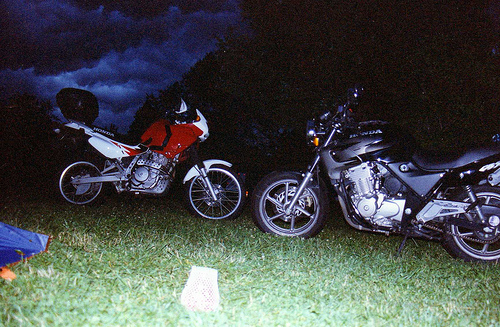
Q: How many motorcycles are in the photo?
A: Two.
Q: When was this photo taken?
A: At night.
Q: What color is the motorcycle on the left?
A: Red and white.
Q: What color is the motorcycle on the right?
A: Black and silver.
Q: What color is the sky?
A: Black.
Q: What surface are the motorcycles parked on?
A: Grass.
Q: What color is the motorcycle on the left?
A: Red and white.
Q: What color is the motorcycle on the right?
A: Gray.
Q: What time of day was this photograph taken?
A: Night.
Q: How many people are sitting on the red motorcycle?
A: 0.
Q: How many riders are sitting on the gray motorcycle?
A: 0.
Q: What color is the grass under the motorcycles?
A: Green.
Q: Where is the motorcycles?
A: On the grass.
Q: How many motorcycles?
A: 2.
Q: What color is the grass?
A: Green.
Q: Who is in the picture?
A: Nobody.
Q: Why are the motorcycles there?
A: Someone parked them there.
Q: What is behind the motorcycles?
A: Trees.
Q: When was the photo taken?
A: At night.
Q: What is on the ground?
A: A candle.